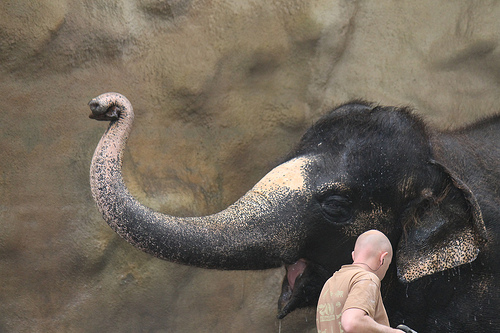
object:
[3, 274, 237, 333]
rock wall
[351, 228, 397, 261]
shaved head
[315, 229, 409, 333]
handler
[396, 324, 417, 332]
hose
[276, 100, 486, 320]
head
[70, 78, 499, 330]
elephant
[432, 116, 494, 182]
back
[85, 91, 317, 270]
trunk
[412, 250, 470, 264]
pigmentations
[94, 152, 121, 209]
pigmentations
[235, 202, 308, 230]
pigmentations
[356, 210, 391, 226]
pigmentations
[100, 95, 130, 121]
pigmentations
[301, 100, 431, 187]
hair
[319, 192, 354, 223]
eye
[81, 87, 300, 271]
trunk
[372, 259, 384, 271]
headphones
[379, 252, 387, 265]
ear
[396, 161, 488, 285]
ear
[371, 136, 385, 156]
??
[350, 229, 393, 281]
head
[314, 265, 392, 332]
shirt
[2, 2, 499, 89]
rock wall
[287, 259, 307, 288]
tongue